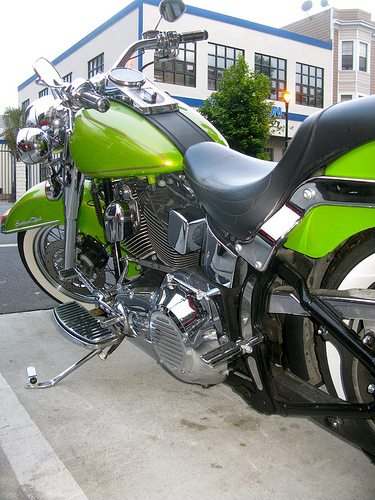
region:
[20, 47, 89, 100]
the left rear view mirror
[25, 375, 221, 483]
the ground is off white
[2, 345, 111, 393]
the kick stand is silver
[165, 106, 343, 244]
the seat is dark grey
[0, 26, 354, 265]
the bike is lime green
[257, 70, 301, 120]
the light is on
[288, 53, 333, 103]
the window pane is black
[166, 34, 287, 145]
the tree is in front of the building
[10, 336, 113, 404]
the kick stand is down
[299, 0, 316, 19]
The satellite is on the building.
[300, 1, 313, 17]
The satellite is round.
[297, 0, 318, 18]
The satellite is gray.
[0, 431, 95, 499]
The white stripe is on the pavement.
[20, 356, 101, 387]
The kick stand is silver.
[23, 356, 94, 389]
The kick stand is metal.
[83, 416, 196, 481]
The pavement is light in color.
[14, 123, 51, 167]
The headlight is silver.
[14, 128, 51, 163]
The head light is made of metal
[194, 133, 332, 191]
The motorcycle seat is black.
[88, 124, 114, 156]
green paint on a tank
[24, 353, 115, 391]
kick stand of a motorcycle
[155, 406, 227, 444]
oil stains on the pavement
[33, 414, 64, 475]
white strip on the pavement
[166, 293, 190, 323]
shiny piece of chrome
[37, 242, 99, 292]
rotor on a wheel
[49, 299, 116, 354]
pedal on a motorcycle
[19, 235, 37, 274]
white wall on a tire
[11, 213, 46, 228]
writing on a motorcycle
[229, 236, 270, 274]
bolts on a motorcycle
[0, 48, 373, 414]
Green motorcycle in front of a building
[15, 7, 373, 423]
green motorcycle parked in front of a building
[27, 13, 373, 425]
green motorcyclein front of a blue and white building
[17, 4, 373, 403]
green motorcycle parked in front of a blue and white building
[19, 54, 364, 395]
green motorcycle with its kick stand out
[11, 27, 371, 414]
green, black and silver motorcycle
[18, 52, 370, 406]
green motorcycle in a parking lot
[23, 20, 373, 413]
green motorcycle in a parking lot next to a building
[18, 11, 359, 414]
motorcycle parked next to a building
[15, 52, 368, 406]
motorcycle parked in a parking lot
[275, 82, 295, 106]
street light in the background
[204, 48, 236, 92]
windows on a building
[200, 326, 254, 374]
foot holder on a motorcycle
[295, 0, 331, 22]
sattelite on a roof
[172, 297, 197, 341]
reflection in chrome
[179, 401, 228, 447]
grease stains on the pavement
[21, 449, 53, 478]
dirty white strip on the parking spot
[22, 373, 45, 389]
bolt on the kickstand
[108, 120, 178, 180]
light shining on the motorcycle tank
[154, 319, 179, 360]
grate on a motorcycle